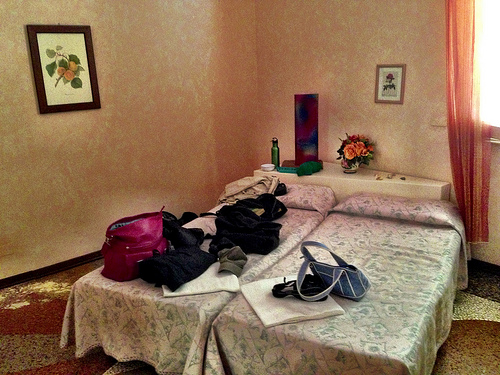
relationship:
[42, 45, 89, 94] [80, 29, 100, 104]
flowers in frame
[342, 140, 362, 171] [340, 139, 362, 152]
vase with flowers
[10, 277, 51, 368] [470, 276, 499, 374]
floor has design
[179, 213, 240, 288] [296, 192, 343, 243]
clothes on bed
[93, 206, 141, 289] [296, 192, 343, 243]
bag on bed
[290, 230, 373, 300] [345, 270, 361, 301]
purse has white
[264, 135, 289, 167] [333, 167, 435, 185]
bottle on table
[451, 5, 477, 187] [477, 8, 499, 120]
curtains at window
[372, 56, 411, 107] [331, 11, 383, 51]
picture hanging on wall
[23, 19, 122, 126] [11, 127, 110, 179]
picture on wall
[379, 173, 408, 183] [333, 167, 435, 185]
rocks on table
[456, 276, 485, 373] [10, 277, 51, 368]
carpet on floor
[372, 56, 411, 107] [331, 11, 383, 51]
art on wall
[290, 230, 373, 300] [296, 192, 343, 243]
purse on bed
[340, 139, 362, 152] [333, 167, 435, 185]
flowers on table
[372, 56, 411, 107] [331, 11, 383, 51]
picture on wall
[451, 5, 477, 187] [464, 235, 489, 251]
curtains have lace